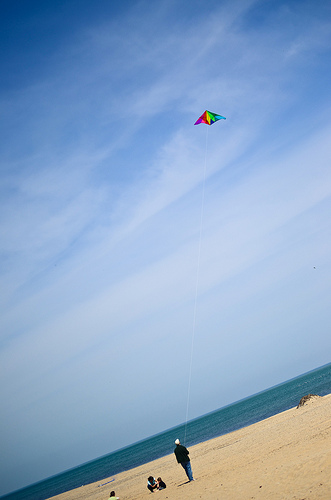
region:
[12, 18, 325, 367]
The sky is clear blue.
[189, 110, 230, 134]
The kite is in the air.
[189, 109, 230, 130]
The kite is colorful.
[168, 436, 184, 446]
He is wearing a hat.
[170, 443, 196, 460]
The shirt is black.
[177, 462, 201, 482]
His jeans are blue.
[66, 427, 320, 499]
The sand is brown.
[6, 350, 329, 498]
The man is on the shore.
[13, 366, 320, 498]
The water is blue.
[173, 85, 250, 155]
kite in the sky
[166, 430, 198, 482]
person on the beach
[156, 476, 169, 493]
person on the beach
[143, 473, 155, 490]
person on the beach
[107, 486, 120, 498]
person on the beach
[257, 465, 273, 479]
patch of sand on beach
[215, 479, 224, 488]
patch of sand on beach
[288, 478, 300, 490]
patch of sand on beach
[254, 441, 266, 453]
patch of sand on beach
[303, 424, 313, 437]
patch of sand on beach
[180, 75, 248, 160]
Kite in the sky.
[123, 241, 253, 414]
String in the air.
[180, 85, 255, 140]
Rainbow colored kite in the sky.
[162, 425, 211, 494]
Man on the sand.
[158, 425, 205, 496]
Man with a hat.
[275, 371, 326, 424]
Hill on the beach.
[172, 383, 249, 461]
Water by the beach.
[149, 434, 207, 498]
Man with a white hat.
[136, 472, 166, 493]
Woman and child.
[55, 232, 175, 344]
white clouds in the sky.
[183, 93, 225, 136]
Rainbow kite in the sky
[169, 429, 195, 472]
Man flying a rainbow sky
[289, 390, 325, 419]
sand dune on a beach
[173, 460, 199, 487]
man wearing blue jeans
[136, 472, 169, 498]
children playing in the stand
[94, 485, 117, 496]
person standing on the beach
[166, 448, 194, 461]
man wearing a black jacket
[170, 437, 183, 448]
man wearing a white shirt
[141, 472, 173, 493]
two children on the beach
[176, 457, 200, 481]
man wearing blue jeans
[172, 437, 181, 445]
man wearing a white hat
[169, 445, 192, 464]
man wearing black shirt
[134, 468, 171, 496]
children in the sand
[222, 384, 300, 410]
water washing up on shore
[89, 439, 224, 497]
people on the beach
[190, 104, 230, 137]
kite in the sky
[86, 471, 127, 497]
kite on the ground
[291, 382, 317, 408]
sand dune in the beach